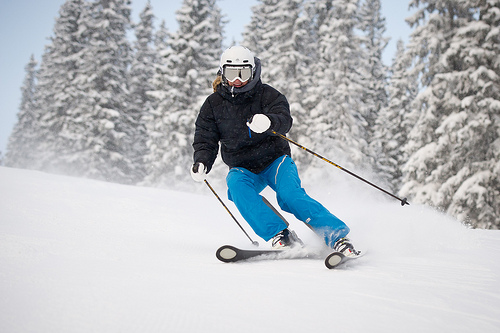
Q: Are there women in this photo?
A: Yes, there is a woman.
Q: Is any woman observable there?
A: Yes, there is a woman.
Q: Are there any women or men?
A: Yes, there is a woman.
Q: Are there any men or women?
A: Yes, there is a woman.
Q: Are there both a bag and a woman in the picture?
A: No, there is a woman but no bags.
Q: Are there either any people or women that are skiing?
A: Yes, the woman is skiing.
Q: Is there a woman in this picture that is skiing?
A: Yes, there is a woman that is skiing.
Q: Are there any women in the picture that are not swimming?
A: Yes, there is a woman that is skiing.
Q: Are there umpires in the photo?
A: No, there are no umpires.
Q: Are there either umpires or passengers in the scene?
A: No, there are no umpires or passengers.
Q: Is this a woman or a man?
A: This is a woman.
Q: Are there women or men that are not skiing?
A: No, there is a woman but she is skiing.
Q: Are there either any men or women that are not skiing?
A: No, there is a woman but she is skiing.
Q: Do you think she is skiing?
A: Yes, the woman is skiing.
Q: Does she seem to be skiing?
A: Yes, the woman is skiing.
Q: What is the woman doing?
A: The woman is skiing.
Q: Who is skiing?
A: The woman is skiing.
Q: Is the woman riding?
A: No, the woman is skiing.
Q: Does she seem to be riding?
A: No, the woman is skiing.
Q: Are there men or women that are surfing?
A: No, there is a woman but she is skiing.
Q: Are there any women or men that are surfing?
A: No, there is a woman but she is skiing.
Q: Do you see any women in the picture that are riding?
A: No, there is a woman but she is skiing.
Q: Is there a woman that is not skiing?
A: No, there is a woman but she is skiing.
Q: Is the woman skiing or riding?
A: The woman is skiing.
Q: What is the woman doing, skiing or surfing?
A: The woman is skiing.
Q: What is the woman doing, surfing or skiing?
A: The woman is skiing.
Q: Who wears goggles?
A: The woman wears goggles.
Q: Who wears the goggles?
A: The woman wears goggles.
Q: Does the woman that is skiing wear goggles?
A: Yes, the woman wears goggles.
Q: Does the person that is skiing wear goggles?
A: Yes, the woman wears goggles.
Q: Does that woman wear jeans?
A: No, the woman wears goggles.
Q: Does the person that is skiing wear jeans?
A: No, the woman wears goggles.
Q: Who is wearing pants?
A: The woman is wearing pants.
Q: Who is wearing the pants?
A: The woman is wearing pants.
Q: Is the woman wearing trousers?
A: Yes, the woman is wearing trousers.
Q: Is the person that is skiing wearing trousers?
A: Yes, the woman is wearing trousers.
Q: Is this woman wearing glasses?
A: No, the woman is wearing trousers.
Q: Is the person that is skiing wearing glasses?
A: No, the woman is wearing trousers.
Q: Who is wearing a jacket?
A: The woman is wearing a jacket.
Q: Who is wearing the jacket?
A: The woman is wearing a jacket.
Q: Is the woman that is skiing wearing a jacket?
A: Yes, the woman is wearing a jacket.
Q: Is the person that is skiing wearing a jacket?
A: Yes, the woman is wearing a jacket.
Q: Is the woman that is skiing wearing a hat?
A: No, the woman is wearing a jacket.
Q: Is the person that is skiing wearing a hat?
A: No, the woman is wearing a jacket.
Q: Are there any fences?
A: No, there are no fences.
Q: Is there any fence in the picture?
A: No, there are no fences.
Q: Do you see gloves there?
A: Yes, there are gloves.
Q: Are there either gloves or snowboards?
A: Yes, there are gloves.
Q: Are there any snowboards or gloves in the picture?
A: Yes, there are gloves.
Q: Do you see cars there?
A: No, there are no cars.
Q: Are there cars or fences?
A: No, there are no cars or fences.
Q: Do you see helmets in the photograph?
A: Yes, there is a helmet.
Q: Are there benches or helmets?
A: Yes, there is a helmet.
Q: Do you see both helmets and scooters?
A: No, there is a helmet but no scooters.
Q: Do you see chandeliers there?
A: No, there are no chandeliers.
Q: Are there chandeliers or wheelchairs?
A: No, there are no chandeliers or wheelchairs.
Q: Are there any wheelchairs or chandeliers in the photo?
A: No, there are no chandeliers or wheelchairs.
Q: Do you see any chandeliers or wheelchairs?
A: No, there are no chandeliers or wheelchairs.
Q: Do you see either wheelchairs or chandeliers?
A: No, there are no chandeliers or wheelchairs.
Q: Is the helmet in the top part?
A: Yes, the helmet is in the top of the image.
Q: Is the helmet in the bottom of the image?
A: No, the helmet is in the top of the image.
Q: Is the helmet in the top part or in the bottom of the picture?
A: The helmet is in the top of the image.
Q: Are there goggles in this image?
A: Yes, there are goggles.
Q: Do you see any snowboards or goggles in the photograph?
A: Yes, there are goggles.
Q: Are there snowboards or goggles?
A: Yes, there are goggles.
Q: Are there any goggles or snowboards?
A: Yes, there are goggles.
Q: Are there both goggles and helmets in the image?
A: Yes, there are both goggles and a helmet.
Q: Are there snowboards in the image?
A: No, there are no snowboards.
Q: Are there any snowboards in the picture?
A: No, there are no snowboards.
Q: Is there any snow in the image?
A: Yes, there is snow.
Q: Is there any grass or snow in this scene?
A: Yes, there is snow.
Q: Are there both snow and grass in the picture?
A: No, there is snow but no grass.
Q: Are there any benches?
A: No, there are no benches.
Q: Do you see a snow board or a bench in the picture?
A: No, there are no benches or snowboards.